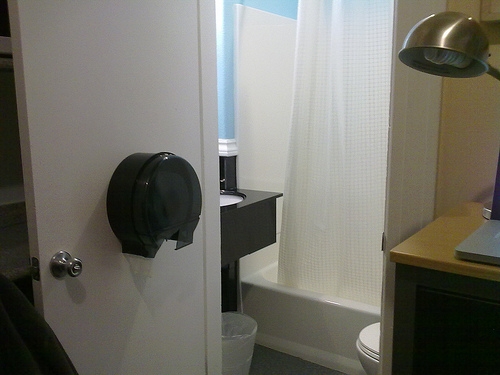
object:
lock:
[74, 265, 81, 270]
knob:
[49, 250, 83, 278]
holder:
[106, 151, 202, 257]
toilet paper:
[145, 173, 188, 241]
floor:
[248, 341, 349, 374]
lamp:
[397, 11, 490, 79]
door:
[6, 0, 221, 374]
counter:
[221, 188, 283, 267]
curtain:
[277, 0, 395, 308]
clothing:
[0, 274, 76, 375]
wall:
[215, 0, 298, 282]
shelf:
[389, 200, 500, 375]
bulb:
[424, 46, 473, 68]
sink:
[220, 192, 246, 207]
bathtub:
[240, 263, 380, 375]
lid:
[355, 321, 380, 375]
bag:
[221, 312, 258, 375]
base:
[455, 220, 500, 265]